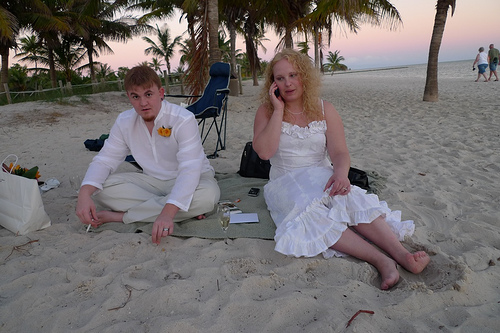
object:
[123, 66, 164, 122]
head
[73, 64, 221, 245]
man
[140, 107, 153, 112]
mouth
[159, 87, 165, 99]
ear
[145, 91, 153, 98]
eye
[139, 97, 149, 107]
nose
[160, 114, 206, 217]
arm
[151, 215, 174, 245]
hand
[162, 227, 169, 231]
ring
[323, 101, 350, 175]
arm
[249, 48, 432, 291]
woman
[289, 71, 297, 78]
eye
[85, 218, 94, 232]
cigarette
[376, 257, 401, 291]
feet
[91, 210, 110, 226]
foot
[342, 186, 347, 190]
ring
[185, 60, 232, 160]
chair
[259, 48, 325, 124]
hair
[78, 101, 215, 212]
shirt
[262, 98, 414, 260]
dress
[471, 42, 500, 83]
couple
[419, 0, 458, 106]
palm trees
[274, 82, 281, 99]
phone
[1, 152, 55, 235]
bag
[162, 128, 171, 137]
flowers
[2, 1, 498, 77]
sky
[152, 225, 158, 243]
finger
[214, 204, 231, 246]
flute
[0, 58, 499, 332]
sand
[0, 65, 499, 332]
beach